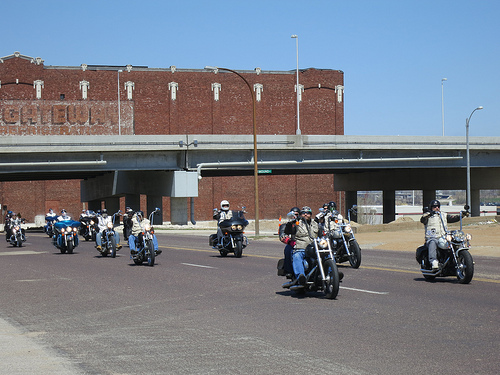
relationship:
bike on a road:
[207, 207, 247, 255] [0, 224, 493, 374]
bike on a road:
[268, 217, 339, 296] [0, 224, 493, 374]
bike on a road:
[412, 212, 477, 285] [0, 224, 493, 374]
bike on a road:
[3, 209, 29, 252] [0, 224, 493, 374]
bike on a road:
[120, 193, 162, 268] [0, 224, 493, 374]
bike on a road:
[52, 209, 82, 251] [0, 224, 493, 374]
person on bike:
[204, 197, 238, 244] [199, 202, 253, 262]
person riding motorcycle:
[204, 197, 238, 244] [205, 209, 257, 257]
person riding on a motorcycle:
[283, 205, 329, 287] [272, 246, 350, 290]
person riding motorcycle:
[283, 205, 329, 287] [277, 212, 339, 299]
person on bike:
[419, 199, 474, 269] [418, 207, 481, 283]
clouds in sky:
[69, 18, 192, 48] [314, 25, 460, 83]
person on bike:
[283, 205, 329, 287] [291, 217, 348, 261]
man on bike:
[214, 200, 245, 245] [208, 205, 248, 256]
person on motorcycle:
[123, 209, 163, 264] [113, 200, 172, 271]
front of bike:
[302, 231, 339, 294] [281, 230, 340, 303]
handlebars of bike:
[424, 199, 476, 241] [416, 204, 474, 280]